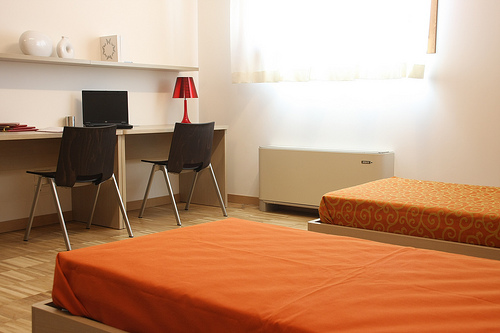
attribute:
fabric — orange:
[51, 216, 498, 332]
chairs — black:
[25, 123, 245, 252]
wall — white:
[1, 1, 200, 229]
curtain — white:
[228, 1, 435, 85]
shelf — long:
[0, 51, 199, 73]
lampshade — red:
[171, 76, 200, 99]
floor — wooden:
[2, 201, 320, 332]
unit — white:
[257, 140, 397, 212]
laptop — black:
[80, 89, 134, 131]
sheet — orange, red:
[52, 217, 498, 332]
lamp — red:
[172, 75, 199, 131]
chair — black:
[22, 125, 135, 252]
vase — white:
[57, 35, 76, 59]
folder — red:
[1, 122, 39, 132]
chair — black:
[138, 121, 230, 225]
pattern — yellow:
[333, 200, 487, 237]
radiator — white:
[257, 143, 395, 211]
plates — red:
[3, 121, 40, 132]